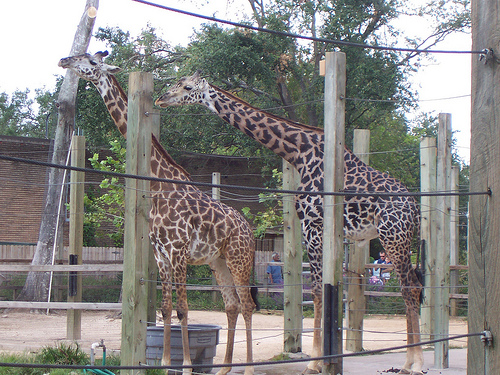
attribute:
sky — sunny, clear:
[6, 3, 496, 49]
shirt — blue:
[266, 267, 283, 284]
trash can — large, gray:
[143, 326, 218, 374]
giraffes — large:
[59, 54, 436, 373]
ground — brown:
[7, 304, 496, 365]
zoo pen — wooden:
[0, 11, 495, 369]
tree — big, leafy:
[66, 142, 154, 246]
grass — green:
[4, 349, 82, 374]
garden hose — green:
[84, 350, 116, 373]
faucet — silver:
[93, 339, 106, 350]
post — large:
[322, 50, 340, 366]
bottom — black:
[321, 283, 344, 371]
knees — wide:
[158, 304, 190, 325]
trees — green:
[133, 7, 439, 178]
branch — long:
[355, 17, 469, 99]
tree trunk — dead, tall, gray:
[23, 1, 103, 307]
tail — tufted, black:
[243, 282, 260, 309]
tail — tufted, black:
[414, 236, 426, 306]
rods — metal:
[278, 40, 488, 55]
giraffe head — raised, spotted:
[58, 50, 119, 89]